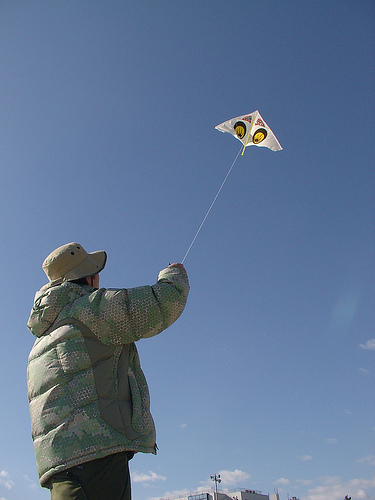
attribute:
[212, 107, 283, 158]
kite — white, triangle shaped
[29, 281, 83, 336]
hood — light green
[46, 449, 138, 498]
trousers — olive green, bunched up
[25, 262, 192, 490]
jacket — puffy, silver, poofy, gray, camoflage patterned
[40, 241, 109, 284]
top hat — beige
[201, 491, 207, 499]
mirror — glass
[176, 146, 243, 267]
string — long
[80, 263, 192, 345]
arm — puffy, held up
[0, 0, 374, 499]
sky — crystal blue, blue, cloudless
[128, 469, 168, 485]
cloud — white, low lying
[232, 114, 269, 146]
design — yellow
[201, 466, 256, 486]
cloud — white